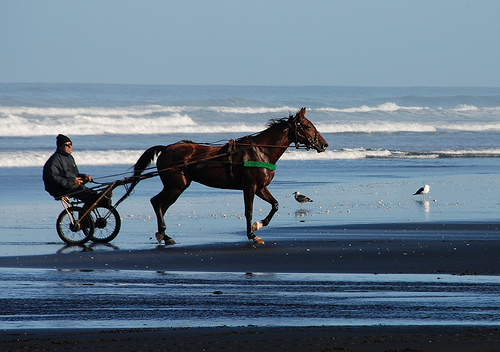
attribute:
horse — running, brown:
[132, 106, 330, 247]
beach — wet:
[1, 167, 499, 351]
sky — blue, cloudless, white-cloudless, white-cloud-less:
[1, 1, 500, 88]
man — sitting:
[41, 132, 112, 229]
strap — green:
[241, 159, 277, 172]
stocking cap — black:
[55, 131, 72, 147]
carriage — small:
[52, 179, 123, 244]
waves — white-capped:
[1, 146, 499, 166]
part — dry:
[0, 326, 499, 351]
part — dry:
[0, 221, 499, 277]